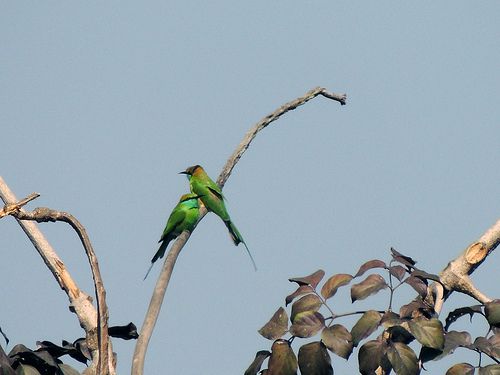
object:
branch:
[132, 85, 347, 372]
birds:
[120, 159, 251, 261]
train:
[365, 22, 457, 95]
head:
[179, 159, 204, 179]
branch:
[234, 63, 361, 142]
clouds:
[392, 31, 459, 112]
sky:
[350, 47, 490, 98]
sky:
[15, 7, 474, 219]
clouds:
[190, 290, 283, 347]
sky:
[9, 9, 472, 334]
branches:
[1, 177, 121, 373]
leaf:
[319, 267, 359, 299]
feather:
[225, 220, 265, 283]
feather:
[145, 241, 168, 281]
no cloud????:
[430, 71, 469, 138]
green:
[196, 180, 211, 187]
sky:
[324, 7, 500, 237]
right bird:
[181, 162, 253, 268]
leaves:
[247, 249, 498, 374]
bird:
[147, 189, 204, 265]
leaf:
[404, 310, 445, 355]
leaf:
[352, 256, 386, 278]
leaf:
[258, 304, 290, 341]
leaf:
[105, 320, 139, 342]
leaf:
[321, 321, 353, 361]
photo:
[0, 4, 500, 375]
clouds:
[0, 0, 500, 164]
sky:
[3, 15, 201, 207]